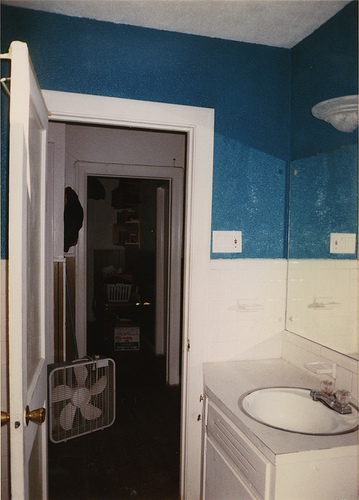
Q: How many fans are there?
A: One.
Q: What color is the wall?
A: Blue and white.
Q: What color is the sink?
A: White.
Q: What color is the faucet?
A: Silver.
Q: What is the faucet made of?
A: Metal.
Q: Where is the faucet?
A: Under the mirror.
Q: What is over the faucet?
A: The mirror.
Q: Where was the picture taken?
A: In a bathroom.